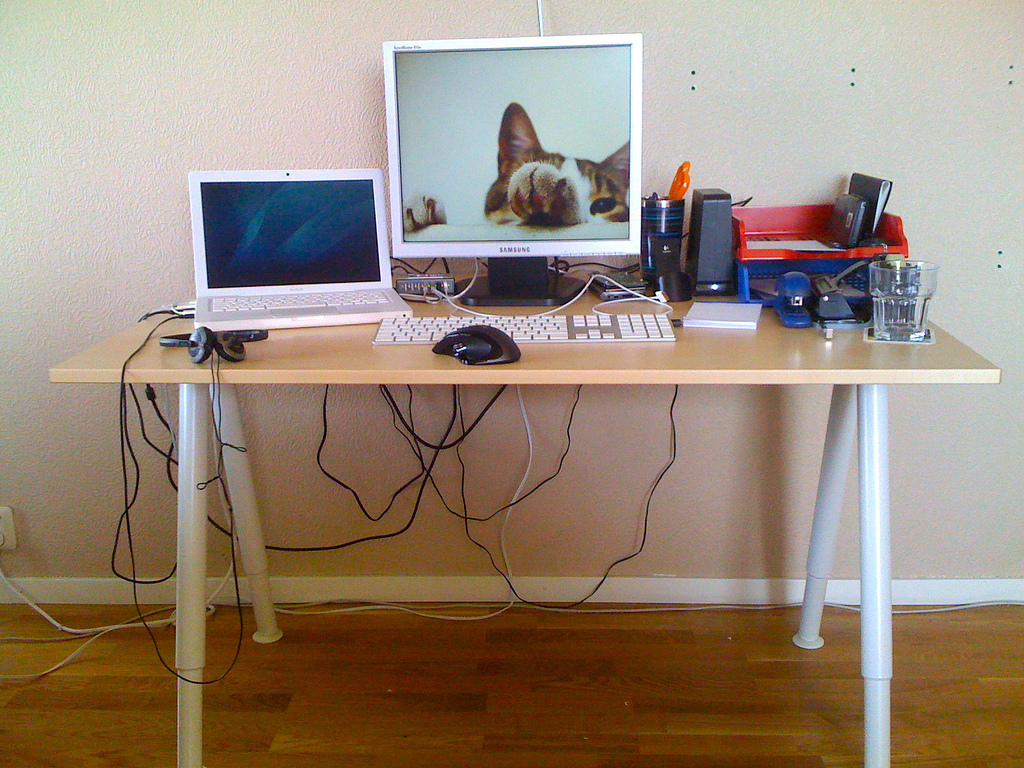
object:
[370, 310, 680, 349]
keyboard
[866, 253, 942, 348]
glass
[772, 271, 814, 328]
stapler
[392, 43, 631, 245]
picture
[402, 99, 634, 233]
cat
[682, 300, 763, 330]
paper pad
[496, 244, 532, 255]
logo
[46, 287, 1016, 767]
desk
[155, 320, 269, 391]
headphones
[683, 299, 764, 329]
pad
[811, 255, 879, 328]
hole punch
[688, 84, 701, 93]
holes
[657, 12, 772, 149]
wall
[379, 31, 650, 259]
monitor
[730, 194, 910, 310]
inboxes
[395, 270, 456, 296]
modem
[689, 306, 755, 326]
paper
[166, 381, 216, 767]
legs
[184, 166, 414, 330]
laptop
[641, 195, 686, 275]
cup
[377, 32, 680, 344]
computer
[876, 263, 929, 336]
empty